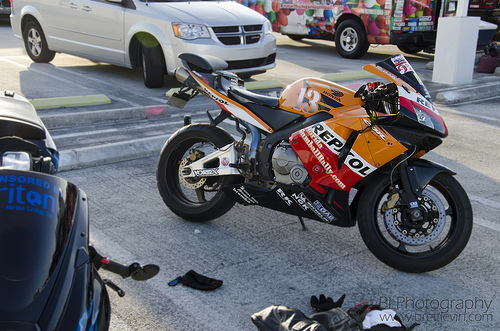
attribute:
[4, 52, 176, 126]
line — white